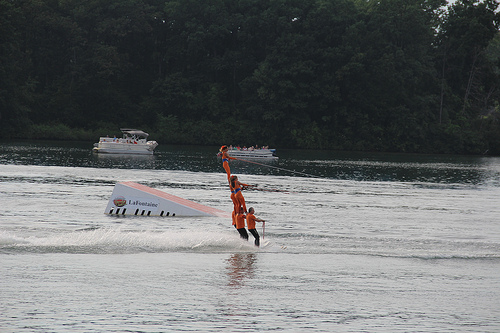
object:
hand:
[245, 185, 251, 188]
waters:
[0, 244, 499, 333]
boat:
[216, 144, 279, 160]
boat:
[92, 128, 159, 154]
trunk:
[462, 62, 477, 118]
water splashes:
[51, 225, 218, 260]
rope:
[231, 147, 497, 274]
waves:
[280, 164, 496, 289]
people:
[210, 139, 266, 246]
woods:
[5, 0, 498, 142]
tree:
[421, 0, 500, 148]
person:
[218, 142, 235, 168]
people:
[226, 143, 268, 150]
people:
[100, 134, 139, 144]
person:
[112, 136, 116, 142]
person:
[114, 139, 121, 143]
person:
[126, 139, 128, 143]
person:
[129, 139, 133, 146]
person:
[133, 141, 137, 148]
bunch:
[109, 139, 145, 146]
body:
[2, 136, 499, 333]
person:
[111, 136, 113, 145]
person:
[116, 137, 118, 142]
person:
[123, 137, 130, 142]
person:
[235, 145, 239, 150]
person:
[242, 146, 246, 150]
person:
[111, 134, 115, 144]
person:
[122, 139, 129, 146]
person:
[134, 139, 139, 146]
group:
[216, 145, 265, 246]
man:
[246, 206, 262, 247]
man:
[236, 208, 250, 240]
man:
[232, 210, 242, 238]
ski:
[263, 242, 270, 252]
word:
[125, 196, 158, 210]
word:
[111, 208, 178, 219]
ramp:
[101, 182, 227, 217]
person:
[231, 179, 255, 205]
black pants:
[249, 229, 261, 247]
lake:
[0, 135, 499, 333]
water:
[3, 144, 495, 328]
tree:
[71, 35, 128, 140]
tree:
[154, 68, 223, 143]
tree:
[258, 30, 336, 153]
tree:
[343, 49, 439, 153]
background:
[3, 0, 499, 151]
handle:
[231, 153, 249, 163]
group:
[216, 144, 271, 160]